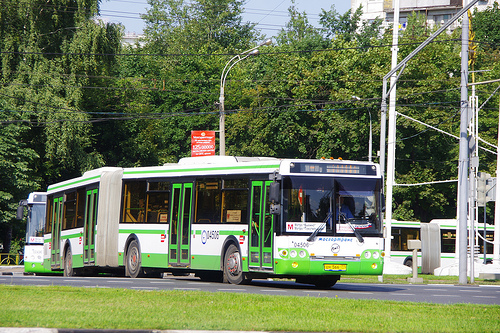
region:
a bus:
[112, 64, 398, 308]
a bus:
[159, 122, 343, 309]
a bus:
[292, 205, 401, 320]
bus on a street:
[37, 146, 399, 289]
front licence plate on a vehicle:
[315, 258, 352, 277]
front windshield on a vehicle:
[278, 168, 388, 243]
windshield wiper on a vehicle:
[300, 190, 337, 248]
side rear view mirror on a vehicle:
[264, 165, 285, 220]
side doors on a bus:
[164, 176, 199, 273]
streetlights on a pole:
[233, 29, 285, 75]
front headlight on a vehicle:
[276, 244, 309, 262]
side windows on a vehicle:
[114, 172, 179, 232]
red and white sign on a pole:
[182, 121, 232, 162]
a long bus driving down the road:
[21, 156, 393, 288]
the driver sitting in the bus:
[331, 200, 353, 227]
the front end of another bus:
[21, 186, 51, 277]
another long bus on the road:
[395, 220, 492, 274]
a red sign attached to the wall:
[186, 126, 218, 158]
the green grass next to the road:
[8, 286, 498, 331]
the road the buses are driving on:
[2, 272, 497, 303]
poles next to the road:
[372, 1, 492, 291]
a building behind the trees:
[354, 2, 494, 27]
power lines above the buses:
[5, 4, 497, 131]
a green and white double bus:
[45, 150, 382, 282]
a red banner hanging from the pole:
[185, 126, 230, 165]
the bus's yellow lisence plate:
[322, 261, 349, 272]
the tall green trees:
[6, 3, 492, 217]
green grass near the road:
[5, 283, 497, 331]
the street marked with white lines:
[2, 271, 498, 305]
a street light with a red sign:
[181, 28, 270, 160]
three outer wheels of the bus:
[51, 231, 249, 288]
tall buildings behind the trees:
[90, 3, 490, 43]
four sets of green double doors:
[47, 177, 282, 269]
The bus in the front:
[41, 155, 388, 290]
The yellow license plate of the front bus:
[322, 260, 349, 273]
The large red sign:
[186, 124, 221, 162]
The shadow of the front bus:
[147, 275, 409, 294]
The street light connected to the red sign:
[217, 34, 274, 156]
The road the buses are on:
[0, 270, 498, 307]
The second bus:
[14, 188, 61, 275]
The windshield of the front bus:
[281, 176, 382, 238]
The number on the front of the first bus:
[288, 238, 310, 248]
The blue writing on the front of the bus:
[315, 233, 357, 245]